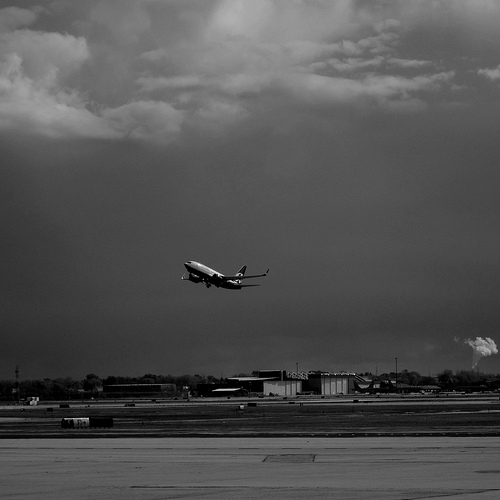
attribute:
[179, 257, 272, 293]
plane — some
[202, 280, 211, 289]
landing gear — plane's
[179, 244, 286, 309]
plane — flying 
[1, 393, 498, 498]
floor — clear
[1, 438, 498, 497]
runways — plane's, one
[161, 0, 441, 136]
clouds — light 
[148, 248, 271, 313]
plane — taking off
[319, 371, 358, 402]
wall — white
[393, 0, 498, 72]
cloud — white 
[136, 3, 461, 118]
cloud — white 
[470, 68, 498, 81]
cloud — white 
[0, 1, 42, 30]
cloud — white 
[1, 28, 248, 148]
cloud — white 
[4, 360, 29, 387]
tower — power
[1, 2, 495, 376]
sky — dark 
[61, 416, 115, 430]
tank — black and white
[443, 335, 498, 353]
smoke — a big cloud